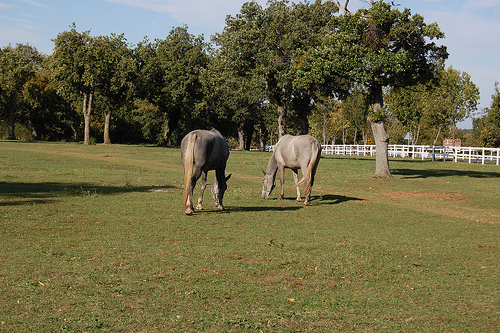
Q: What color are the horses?
A: Gray.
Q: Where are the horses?
A: In a field.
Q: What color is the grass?
A: Green.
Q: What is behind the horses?
A: Trees.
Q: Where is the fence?
A: Behind the trees.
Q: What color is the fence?
A: White.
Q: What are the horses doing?
A: Eating grass.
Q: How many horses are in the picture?
A: Two.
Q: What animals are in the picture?
A: Two horses grazing side by side.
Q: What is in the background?
A: A group of trees with green leaves.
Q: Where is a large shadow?
A: On the ground.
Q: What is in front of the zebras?
A: Tall green leafy trees.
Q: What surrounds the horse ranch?
A: White fence.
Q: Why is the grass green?
A: For horses to graze on.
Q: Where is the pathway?
A: It is made through the grassy area.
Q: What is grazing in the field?
A: A couple of gray horses.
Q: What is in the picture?
A: A green field with brown leaves scattered throughout.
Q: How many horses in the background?
A: 2.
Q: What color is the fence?
A: White.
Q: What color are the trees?
A: Green.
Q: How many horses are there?
A: Two.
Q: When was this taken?
A: Daytime.